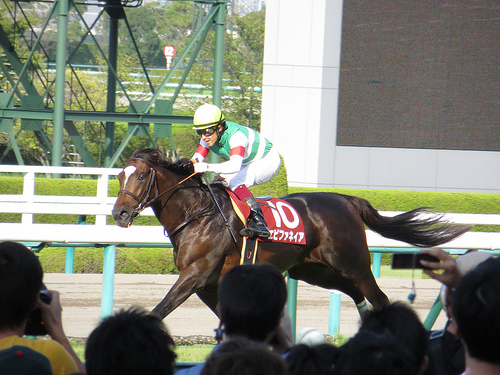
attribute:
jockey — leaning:
[185, 101, 283, 245]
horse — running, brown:
[112, 144, 473, 325]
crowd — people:
[3, 238, 499, 373]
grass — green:
[4, 175, 499, 271]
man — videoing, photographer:
[0, 238, 86, 374]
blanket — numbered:
[223, 188, 311, 248]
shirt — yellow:
[0, 336, 84, 375]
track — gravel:
[41, 267, 461, 334]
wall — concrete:
[258, 5, 499, 192]